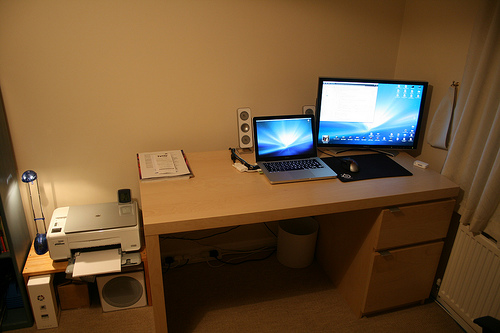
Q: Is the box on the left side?
A: Yes, the box is on the left of the image.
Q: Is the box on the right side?
A: No, the box is on the left of the image.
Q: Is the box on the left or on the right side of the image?
A: The box is on the left of the image.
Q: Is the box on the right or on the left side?
A: The box is on the left of the image.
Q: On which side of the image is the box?
A: The box is on the left of the image.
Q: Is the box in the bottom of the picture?
A: Yes, the box is in the bottom of the image.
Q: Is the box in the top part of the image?
A: No, the box is in the bottom of the image.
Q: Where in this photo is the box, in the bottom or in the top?
A: The box is in the bottom of the image.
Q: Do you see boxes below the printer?
A: Yes, there is a box below the printer.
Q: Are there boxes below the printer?
A: Yes, there is a box below the printer.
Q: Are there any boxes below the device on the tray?
A: Yes, there is a box below the printer.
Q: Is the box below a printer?
A: Yes, the box is below a printer.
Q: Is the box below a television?
A: No, the box is below a printer.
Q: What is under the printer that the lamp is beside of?
A: The box is under the printer.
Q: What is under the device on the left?
A: The box is under the printer.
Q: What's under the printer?
A: The box is under the printer.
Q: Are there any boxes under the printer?
A: Yes, there is a box under the printer.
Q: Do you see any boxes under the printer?
A: Yes, there is a box under the printer.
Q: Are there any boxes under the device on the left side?
A: Yes, there is a box under the printer.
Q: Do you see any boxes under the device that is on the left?
A: Yes, there is a box under the printer.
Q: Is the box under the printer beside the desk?
A: Yes, the box is under the printer.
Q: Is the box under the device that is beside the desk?
A: Yes, the box is under the printer.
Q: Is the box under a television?
A: No, the box is under the printer.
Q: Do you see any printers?
A: Yes, there is a printer.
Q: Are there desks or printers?
A: Yes, there is a printer.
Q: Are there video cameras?
A: No, there are no video cameras.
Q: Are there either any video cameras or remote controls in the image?
A: No, there are no video cameras or remote controls.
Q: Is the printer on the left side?
A: Yes, the printer is on the left of the image.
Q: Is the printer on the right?
A: No, the printer is on the left of the image.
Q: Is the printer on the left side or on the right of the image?
A: The printer is on the left of the image.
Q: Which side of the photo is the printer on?
A: The printer is on the left of the image.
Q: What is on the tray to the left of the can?
A: The printer is on the tray.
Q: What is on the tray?
A: The printer is on the tray.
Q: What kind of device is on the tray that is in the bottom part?
A: The device is a printer.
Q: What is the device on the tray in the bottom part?
A: The device is a printer.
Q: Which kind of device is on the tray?
A: The device is a printer.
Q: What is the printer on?
A: The printer is on the tray.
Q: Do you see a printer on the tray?
A: Yes, there is a printer on the tray.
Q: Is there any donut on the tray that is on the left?
A: No, there is a printer on the tray.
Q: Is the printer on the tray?
A: Yes, the printer is on the tray.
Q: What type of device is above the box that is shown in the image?
A: The device is a printer.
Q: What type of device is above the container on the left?
A: The device is a printer.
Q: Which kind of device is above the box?
A: The device is a printer.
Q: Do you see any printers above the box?
A: Yes, there is a printer above the box.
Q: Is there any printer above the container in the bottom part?
A: Yes, there is a printer above the box.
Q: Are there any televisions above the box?
A: No, there is a printer above the box.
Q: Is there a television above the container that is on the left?
A: No, there is a printer above the box.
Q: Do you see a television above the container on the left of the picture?
A: No, there is a printer above the box.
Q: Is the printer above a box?
A: Yes, the printer is above a box.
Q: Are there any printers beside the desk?
A: Yes, there is a printer beside the desk.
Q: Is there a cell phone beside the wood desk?
A: No, there is a printer beside the desk.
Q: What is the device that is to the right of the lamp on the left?
A: The device is a printer.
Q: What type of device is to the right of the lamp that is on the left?
A: The device is a printer.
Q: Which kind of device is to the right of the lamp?
A: The device is a printer.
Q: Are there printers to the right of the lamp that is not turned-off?
A: Yes, there is a printer to the right of the lamp.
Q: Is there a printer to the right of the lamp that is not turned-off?
A: Yes, there is a printer to the right of the lamp.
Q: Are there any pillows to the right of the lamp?
A: No, there is a printer to the right of the lamp.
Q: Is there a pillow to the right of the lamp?
A: No, there is a printer to the right of the lamp.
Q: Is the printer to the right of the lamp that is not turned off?
A: Yes, the printer is to the right of the lamp.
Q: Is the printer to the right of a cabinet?
A: No, the printer is to the right of the lamp.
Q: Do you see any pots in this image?
A: No, there are no pots.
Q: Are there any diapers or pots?
A: No, there are no pots or diapers.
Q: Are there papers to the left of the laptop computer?
A: Yes, there are papers to the left of the laptop computer.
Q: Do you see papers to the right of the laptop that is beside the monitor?
A: No, the papers are to the left of the laptop.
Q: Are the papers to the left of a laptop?
A: Yes, the papers are to the left of a laptop.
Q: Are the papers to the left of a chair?
A: No, the papers are to the left of a laptop.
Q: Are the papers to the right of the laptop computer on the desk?
A: No, the papers are to the left of the laptop.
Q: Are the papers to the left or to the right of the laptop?
A: The papers are to the left of the laptop.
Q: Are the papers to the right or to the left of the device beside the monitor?
A: The papers are to the left of the laptop.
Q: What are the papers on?
A: The papers are on the desk.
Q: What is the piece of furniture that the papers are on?
A: The piece of furniture is a desk.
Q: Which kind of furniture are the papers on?
A: The papers are on the desk.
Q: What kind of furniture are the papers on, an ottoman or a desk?
A: The papers are on a desk.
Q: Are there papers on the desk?
A: Yes, there are papers on the desk.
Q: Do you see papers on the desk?
A: Yes, there are papers on the desk.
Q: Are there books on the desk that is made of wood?
A: No, there are papers on the desk.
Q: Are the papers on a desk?
A: Yes, the papers are on a desk.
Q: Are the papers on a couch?
A: No, the papers are on a desk.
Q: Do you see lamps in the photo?
A: Yes, there is a lamp.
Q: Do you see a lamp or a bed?
A: Yes, there is a lamp.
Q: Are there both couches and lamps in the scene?
A: No, there is a lamp but no couches.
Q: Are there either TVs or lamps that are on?
A: Yes, the lamp is on.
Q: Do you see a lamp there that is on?
A: Yes, there is a lamp that is on.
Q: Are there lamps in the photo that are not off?
A: Yes, there is a lamp that is on.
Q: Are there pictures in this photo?
A: No, there are no pictures.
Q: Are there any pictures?
A: No, there are no pictures.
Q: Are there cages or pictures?
A: No, there are no pictures or cages.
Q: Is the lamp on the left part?
A: Yes, the lamp is on the left of the image.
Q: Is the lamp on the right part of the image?
A: No, the lamp is on the left of the image.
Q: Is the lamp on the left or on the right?
A: The lamp is on the left of the image.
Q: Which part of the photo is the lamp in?
A: The lamp is on the left of the image.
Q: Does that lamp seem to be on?
A: Yes, the lamp is on.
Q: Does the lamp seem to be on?
A: Yes, the lamp is on.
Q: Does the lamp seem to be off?
A: No, the lamp is on.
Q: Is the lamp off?
A: No, the lamp is on.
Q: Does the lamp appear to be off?
A: No, the lamp is on.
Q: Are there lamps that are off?
A: No, there is a lamp but it is on.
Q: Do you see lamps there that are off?
A: No, there is a lamp but it is on.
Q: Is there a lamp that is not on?
A: No, there is a lamp but it is on.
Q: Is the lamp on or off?
A: The lamp is on.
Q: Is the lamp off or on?
A: The lamp is on.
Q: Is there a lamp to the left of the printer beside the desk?
A: Yes, there is a lamp to the left of the printer.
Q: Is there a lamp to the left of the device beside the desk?
A: Yes, there is a lamp to the left of the printer.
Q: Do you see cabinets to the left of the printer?
A: No, there is a lamp to the left of the printer.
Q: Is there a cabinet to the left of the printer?
A: No, there is a lamp to the left of the printer.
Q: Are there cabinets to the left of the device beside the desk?
A: No, there is a lamp to the left of the printer.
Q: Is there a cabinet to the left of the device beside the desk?
A: No, there is a lamp to the left of the printer.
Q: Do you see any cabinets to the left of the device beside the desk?
A: No, there is a lamp to the left of the printer.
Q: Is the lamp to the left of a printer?
A: Yes, the lamp is to the left of a printer.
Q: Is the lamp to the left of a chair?
A: No, the lamp is to the left of a printer.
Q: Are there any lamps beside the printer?
A: Yes, there is a lamp beside the printer.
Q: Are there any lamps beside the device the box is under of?
A: Yes, there is a lamp beside the printer.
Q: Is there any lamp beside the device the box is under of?
A: Yes, there is a lamp beside the printer.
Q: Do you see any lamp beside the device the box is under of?
A: Yes, there is a lamp beside the printer.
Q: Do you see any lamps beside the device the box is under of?
A: Yes, there is a lamp beside the printer.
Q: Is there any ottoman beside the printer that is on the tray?
A: No, there is a lamp beside the printer.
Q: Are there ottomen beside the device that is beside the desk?
A: No, there is a lamp beside the printer.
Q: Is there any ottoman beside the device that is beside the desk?
A: No, there is a lamp beside the printer.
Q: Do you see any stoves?
A: No, there are no stoves.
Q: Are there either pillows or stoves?
A: No, there are no stoves or pillows.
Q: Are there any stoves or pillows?
A: No, there are no stoves or pillows.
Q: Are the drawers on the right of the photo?
A: Yes, the drawers are on the right of the image.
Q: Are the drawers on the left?
A: No, the drawers are on the right of the image.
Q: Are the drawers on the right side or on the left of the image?
A: The drawers are on the right of the image.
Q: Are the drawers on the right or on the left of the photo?
A: The drawers are on the right of the image.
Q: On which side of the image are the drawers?
A: The drawers are on the right of the image.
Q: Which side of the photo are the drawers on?
A: The drawers are on the right of the image.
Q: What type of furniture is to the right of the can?
A: The pieces of furniture are drawers.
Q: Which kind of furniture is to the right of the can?
A: The pieces of furniture are drawers.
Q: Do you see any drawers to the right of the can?
A: Yes, there are drawers to the right of the can.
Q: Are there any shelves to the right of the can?
A: No, there are drawers to the right of the can.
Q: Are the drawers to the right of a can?
A: Yes, the drawers are to the right of a can.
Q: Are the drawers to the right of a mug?
A: No, the drawers are to the right of a can.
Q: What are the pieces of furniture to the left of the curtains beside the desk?
A: The pieces of furniture are drawers.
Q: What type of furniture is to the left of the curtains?
A: The pieces of furniture are drawers.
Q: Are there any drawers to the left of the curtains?
A: Yes, there are drawers to the left of the curtains.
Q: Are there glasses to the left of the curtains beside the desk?
A: No, there are drawers to the left of the curtains.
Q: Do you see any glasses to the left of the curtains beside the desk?
A: No, there are drawers to the left of the curtains.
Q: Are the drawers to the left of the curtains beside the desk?
A: Yes, the drawers are to the left of the curtains.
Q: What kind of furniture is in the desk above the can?
A: The pieces of furniture are drawers.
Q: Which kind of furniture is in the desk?
A: The pieces of furniture are drawers.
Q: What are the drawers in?
A: The drawers are in the desk.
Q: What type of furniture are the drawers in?
A: The drawers are in the desk.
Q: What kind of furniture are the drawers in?
A: The drawers are in the desk.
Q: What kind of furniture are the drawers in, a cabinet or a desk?
A: The drawers are in a desk.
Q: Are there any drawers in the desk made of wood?
A: Yes, there are drawers in the desk.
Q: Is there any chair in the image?
A: No, there are no chairs.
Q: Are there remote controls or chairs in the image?
A: No, there are no chairs or remote controls.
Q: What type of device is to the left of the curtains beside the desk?
A: The device is a monitor.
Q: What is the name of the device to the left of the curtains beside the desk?
A: The device is a monitor.